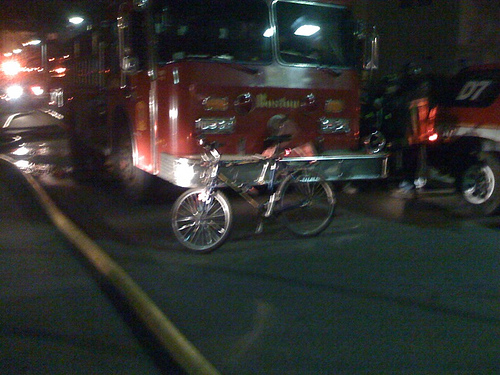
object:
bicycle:
[162, 116, 338, 253]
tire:
[449, 156, 499, 219]